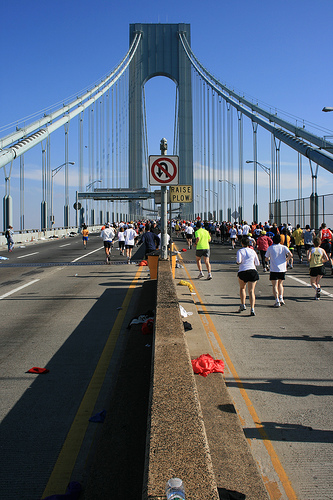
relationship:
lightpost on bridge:
[162, 129, 175, 213] [25, 115, 297, 500]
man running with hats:
[264, 231, 293, 306] [92, 222, 136, 234]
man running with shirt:
[143, 212, 241, 314] [196, 227, 208, 251]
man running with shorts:
[143, 212, 241, 314] [197, 246, 209, 258]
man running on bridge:
[264, 231, 293, 306] [219, 313, 320, 453]